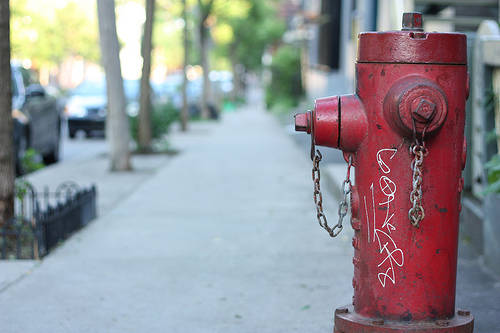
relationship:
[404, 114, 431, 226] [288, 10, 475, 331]
chain on fire hydrant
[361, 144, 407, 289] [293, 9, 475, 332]
graffiti on fire hydrant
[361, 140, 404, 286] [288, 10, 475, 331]
graffiti on fire hydrant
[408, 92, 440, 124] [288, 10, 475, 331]
bolt on fire hydrant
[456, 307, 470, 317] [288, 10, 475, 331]
bolt on fire hydrant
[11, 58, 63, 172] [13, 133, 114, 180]
car parked near parking space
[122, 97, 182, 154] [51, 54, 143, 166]
bush near car.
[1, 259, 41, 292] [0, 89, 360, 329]
crack in sidewalk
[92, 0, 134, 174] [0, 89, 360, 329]
tree sticking out of sidewalk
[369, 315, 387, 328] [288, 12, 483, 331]
bolt on hydrant